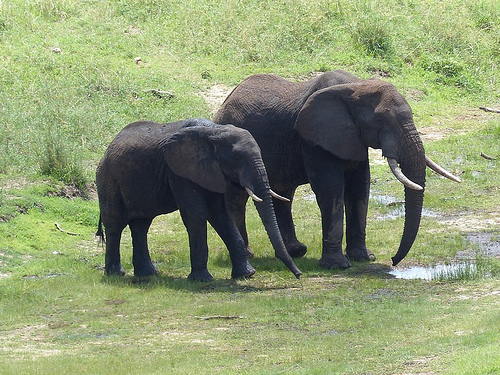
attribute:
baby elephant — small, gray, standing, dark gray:
[93, 120, 304, 283]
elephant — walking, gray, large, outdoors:
[216, 66, 462, 272]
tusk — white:
[243, 187, 264, 204]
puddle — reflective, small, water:
[373, 261, 477, 283]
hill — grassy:
[3, 2, 500, 252]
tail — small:
[96, 209, 106, 240]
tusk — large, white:
[389, 157, 424, 193]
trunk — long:
[390, 117, 427, 266]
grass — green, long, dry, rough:
[1, 3, 499, 374]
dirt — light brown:
[2, 318, 258, 363]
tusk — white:
[268, 188, 293, 203]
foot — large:
[321, 255, 353, 270]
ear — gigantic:
[292, 84, 368, 161]